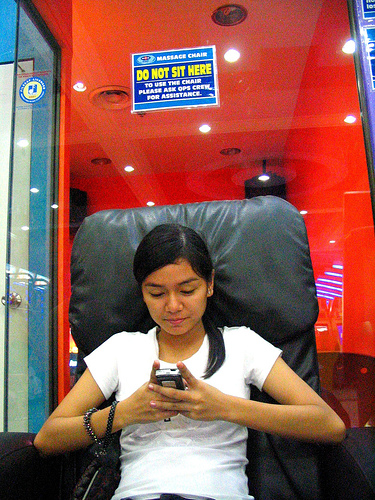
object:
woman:
[29, 216, 352, 499]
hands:
[147, 355, 213, 426]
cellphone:
[153, 360, 185, 396]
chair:
[0, 185, 373, 500]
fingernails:
[149, 382, 155, 390]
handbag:
[66, 384, 123, 500]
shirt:
[82, 323, 285, 500]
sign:
[123, 42, 221, 116]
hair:
[130, 219, 227, 382]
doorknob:
[0, 290, 24, 315]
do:
[135, 68, 150, 83]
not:
[150, 65, 171, 81]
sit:
[170, 63, 186, 79]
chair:
[180, 75, 203, 87]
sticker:
[18, 75, 47, 107]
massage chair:
[155, 50, 208, 62]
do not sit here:
[135, 62, 212, 83]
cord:
[82, 399, 120, 458]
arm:
[29, 349, 133, 458]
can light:
[220, 42, 243, 68]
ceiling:
[73, 0, 320, 203]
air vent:
[85, 82, 135, 116]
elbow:
[321, 404, 353, 448]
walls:
[28, 0, 373, 408]